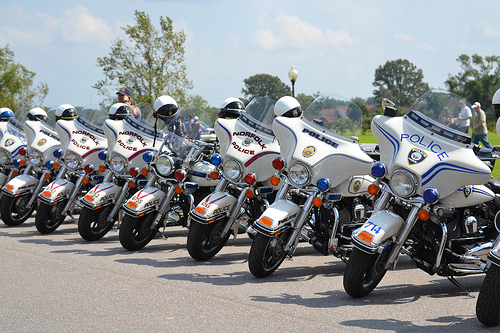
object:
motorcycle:
[249, 92, 382, 274]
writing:
[401, 132, 450, 161]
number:
[362, 220, 382, 235]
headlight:
[391, 170, 418, 197]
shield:
[405, 88, 475, 135]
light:
[366, 182, 380, 196]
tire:
[344, 245, 390, 297]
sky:
[1, 0, 499, 111]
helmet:
[153, 97, 179, 117]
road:
[0, 213, 499, 332]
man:
[455, 100, 472, 133]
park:
[0, 10, 499, 183]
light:
[286, 67, 299, 82]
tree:
[374, 58, 429, 115]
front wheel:
[250, 230, 287, 277]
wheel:
[184, 217, 230, 261]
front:
[189, 188, 235, 262]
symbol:
[302, 146, 314, 157]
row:
[1, 94, 499, 326]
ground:
[0, 210, 499, 333]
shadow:
[160, 254, 420, 286]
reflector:
[359, 230, 372, 243]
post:
[290, 79, 297, 96]